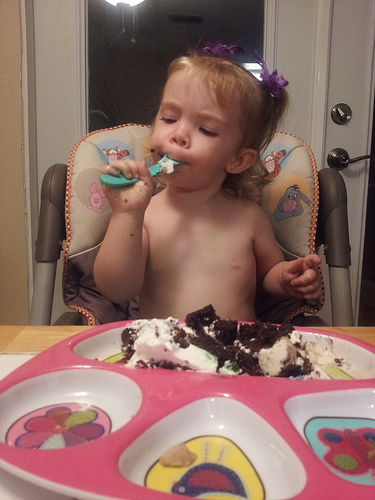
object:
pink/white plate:
[0, 317, 374, 498]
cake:
[118, 302, 329, 380]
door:
[22, 0, 373, 330]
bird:
[170, 442, 249, 496]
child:
[93, 42, 323, 328]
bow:
[252, 53, 288, 95]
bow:
[199, 41, 240, 59]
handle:
[326, 146, 371, 172]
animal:
[269, 183, 312, 222]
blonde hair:
[142, 43, 291, 207]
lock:
[329, 101, 353, 127]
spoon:
[97, 154, 182, 188]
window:
[88, 0, 265, 141]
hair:
[139, 39, 292, 205]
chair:
[30, 122, 355, 328]